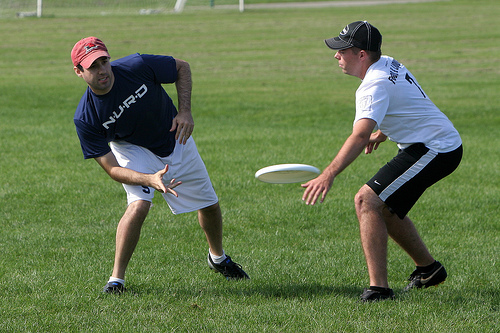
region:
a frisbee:
[252, 161, 317, 183]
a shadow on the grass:
[199, 282, 328, 297]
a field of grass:
[217, 25, 288, 112]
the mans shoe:
[205, 257, 251, 277]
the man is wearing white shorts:
[176, 159, 206, 201]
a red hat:
[71, 38, 98, 60]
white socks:
[211, 251, 224, 263]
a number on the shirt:
[406, 70, 430, 103]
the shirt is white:
[395, 95, 428, 134]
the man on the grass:
[47, 26, 254, 294]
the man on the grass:
[300, 13, 470, 322]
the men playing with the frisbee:
[46, 13, 457, 308]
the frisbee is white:
[232, 143, 322, 204]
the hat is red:
[55, 29, 125, 95]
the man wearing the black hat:
[295, 6, 392, 72]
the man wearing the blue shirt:
[64, 49, 195, 161]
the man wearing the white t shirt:
[344, 59, 456, 164]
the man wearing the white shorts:
[89, 129, 229, 216]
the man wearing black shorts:
[343, 133, 469, 228]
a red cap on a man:
[71, 33, 111, 69]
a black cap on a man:
[319, 20, 382, 54]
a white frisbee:
[251, 158, 325, 185]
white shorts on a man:
[110, 124, 220, 210]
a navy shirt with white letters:
[73, 52, 181, 169]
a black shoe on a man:
[203, 251, 255, 284]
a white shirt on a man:
[352, 51, 465, 154]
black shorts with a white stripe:
[361, 138, 470, 219]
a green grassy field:
[1, 0, 497, 331]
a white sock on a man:
[205, 245, 227, 266]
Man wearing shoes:
[84, 250, 254, 302]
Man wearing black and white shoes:
[328, 264, 454, 316]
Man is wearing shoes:
[336, 262, 454, 309]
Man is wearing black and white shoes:
[335, 264, 450, 308]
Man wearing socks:
[356, 255, 436, 291]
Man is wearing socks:
[351, 260, 432, 291]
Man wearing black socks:
[353, 257, 440, 294]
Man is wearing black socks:
[363, 255, 445, 292]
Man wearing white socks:
[90, 247, 230, 286]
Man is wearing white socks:
[97, 243, 229, 290]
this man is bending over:
[56, 25, 258, 296]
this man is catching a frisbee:
[235, 17, 496, 263]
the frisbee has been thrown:
[237, 145, 351, 217]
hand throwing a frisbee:
[117, 150, 200, 218]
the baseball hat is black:
[300, 18, 478, 128]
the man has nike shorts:
[319, 16, 474, 258]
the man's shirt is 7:
[312, 15, 481, 206]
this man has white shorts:
[63, 44, 240, 239]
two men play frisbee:
[47, 28, 450, 263]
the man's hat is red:
[59, 33, 140, 88]